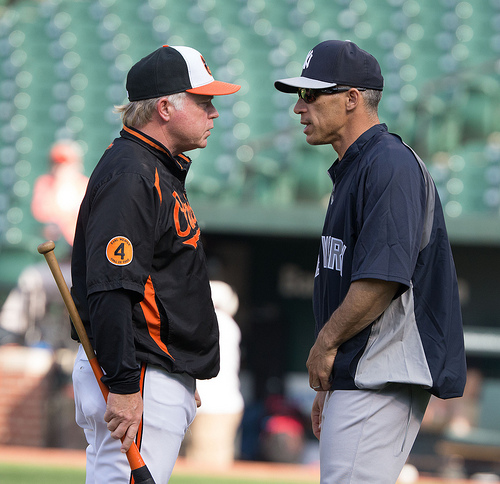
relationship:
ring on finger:
[300, 373, 345, 400] [293, 374, 349, 422]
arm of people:
[333, 233, 454, 342] [255, 21, 471, 484]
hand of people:
[294, 302, 365, 395] [255, 21, 471, 484]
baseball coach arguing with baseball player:
[71, 44, 240, 482] [277, 38, 467, 482]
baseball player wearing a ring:
[277, 38, 467, 482] [300, 373, 345, 400]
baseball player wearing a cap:
[277, 38, 467, 482] [256, 23, 401, 100]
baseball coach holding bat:
[71, 44, 240, 482] [12, 238, 135, 401]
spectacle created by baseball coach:
[22, 123, 94, 196] [71, 44, 240, 482]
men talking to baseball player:
[56, 11, 451, 271] [277, 38, 467, 482]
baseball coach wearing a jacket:
[71, 44, 240, 482] [80, 137, 237, 360]